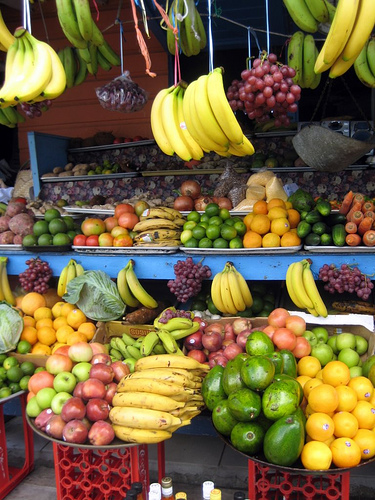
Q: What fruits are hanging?
A: Grapes and bananas.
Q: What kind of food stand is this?
A: Fruit.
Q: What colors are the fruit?
A: Yellow, green, red, purple, orange.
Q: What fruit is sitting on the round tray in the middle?
A: Apples.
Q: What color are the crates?
A: Red.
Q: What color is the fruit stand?
A: Blue.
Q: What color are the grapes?
A: Purple.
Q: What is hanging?
A: Grapes and bananas.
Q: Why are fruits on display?
A: To buy and sell.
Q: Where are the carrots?
A: On the far right.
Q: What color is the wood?
A: Blue.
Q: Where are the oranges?
A: Between the limes and the cucumbers.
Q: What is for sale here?
A: Fruits and vegetables.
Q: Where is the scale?
A: Hanging on the right.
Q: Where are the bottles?
A: In the center, on the ground.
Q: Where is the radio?
A: At the top of the booth, on the right.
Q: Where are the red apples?
A: In the bowl on the left.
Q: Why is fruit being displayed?
A: To be sold.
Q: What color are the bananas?
A: Yellow.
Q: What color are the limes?
A: Green.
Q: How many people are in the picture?
A: No people.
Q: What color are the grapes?
A: Red.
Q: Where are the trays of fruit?
A: On red stands.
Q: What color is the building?
A: Red.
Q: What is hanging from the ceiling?
A: Fruit.